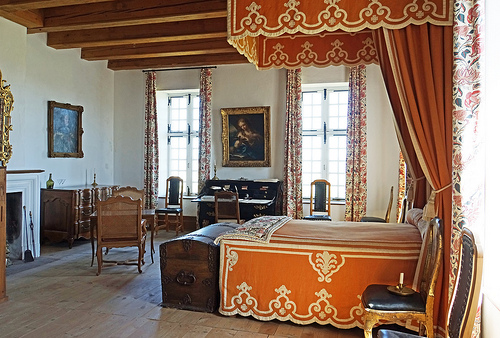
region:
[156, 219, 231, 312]
large brown wooden trunk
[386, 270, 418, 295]
white candle on a chair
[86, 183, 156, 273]
small table with two chairs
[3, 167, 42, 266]
white framed fireplace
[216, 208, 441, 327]
orange decorated bedspread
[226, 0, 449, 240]
orange bed canope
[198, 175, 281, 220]
brown wooden desk with chair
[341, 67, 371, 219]
long flowered curtain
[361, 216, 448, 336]
wooden chair with black cushion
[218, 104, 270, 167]
gold framed painting of a lady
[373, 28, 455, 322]
The red curtains beside the bed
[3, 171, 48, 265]
The white fireplace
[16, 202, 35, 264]
The fireplace shovel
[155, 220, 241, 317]
The trunk at the foot of the bed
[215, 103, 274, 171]
The painting between the two windows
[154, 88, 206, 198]
The window on the left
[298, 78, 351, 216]
The window on the right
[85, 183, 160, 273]
The table and chairs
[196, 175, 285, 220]
The desk between the two windows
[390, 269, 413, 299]
Candle on the black seat of a chair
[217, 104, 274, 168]
Painting on wall with fancy frame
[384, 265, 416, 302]
Candle holder with candle on chair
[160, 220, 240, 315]
Wooden chest at foot of bed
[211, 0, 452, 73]
Fancy bed canopy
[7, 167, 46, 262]
Fireplace in bedroom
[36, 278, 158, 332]
Wooden floors in bedroom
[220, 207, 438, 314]
Bed with fancy sheets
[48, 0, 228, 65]
Wooden beams on ceiling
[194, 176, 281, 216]
Black writing desk in bedroom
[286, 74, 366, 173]
Drawn curtains in bedroom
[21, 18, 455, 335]
One bed is in the room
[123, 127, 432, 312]
There is a chess in front of the bed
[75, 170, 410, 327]
Multiple chairs are in the room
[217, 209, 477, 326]
A chair is next to the bed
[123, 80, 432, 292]
Two windows are visible in the photo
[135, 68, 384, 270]
The windows are long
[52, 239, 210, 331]
The floor is hardwood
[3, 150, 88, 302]
A fireplace is in the room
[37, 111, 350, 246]
The walls are white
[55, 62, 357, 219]
Two paintings on the walls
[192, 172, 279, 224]
Black desk under the gold frame with the woman pictured.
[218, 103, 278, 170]
Gold frame on the wall with the woman in the picture above the black desk.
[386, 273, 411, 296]
Candlestick on the gold dish on the wooden chair.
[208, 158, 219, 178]
Candlestick on the black desk.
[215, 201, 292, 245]
Floral patterned blanket on the orange bedspread.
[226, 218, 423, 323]
Orange and cream colored bed spread.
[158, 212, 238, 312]
Wooden trunk at the foot of the bed.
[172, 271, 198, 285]
Handle on the wooden trunk at the foot of the bed.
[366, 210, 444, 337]
Wooden chair with the candlestick on the seat.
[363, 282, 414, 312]
The black seat where the candlestick is placed.